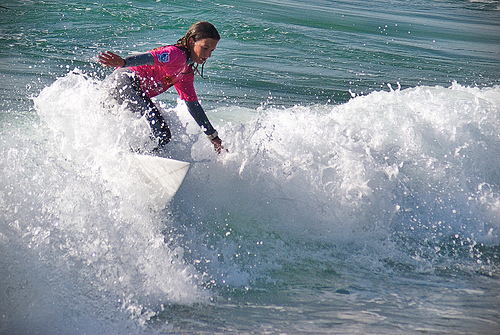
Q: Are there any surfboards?
A: Yes, there is a surfboard.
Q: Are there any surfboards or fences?
A: Yes, there is a surfboard.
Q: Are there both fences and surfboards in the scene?
A: No, there is a surfboard but no fences.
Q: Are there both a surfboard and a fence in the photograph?
A: No, there is a surfboard but no fences.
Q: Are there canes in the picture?
A: No, there are no canes.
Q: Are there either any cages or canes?
A: No, there are no canes or cages.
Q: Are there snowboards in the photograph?
A: No, there are no snowboards.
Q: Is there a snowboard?
A: No, there are no snowboards.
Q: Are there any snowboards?
A: No, there are no snowboards.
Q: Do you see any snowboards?
A: No, there are no snowboards.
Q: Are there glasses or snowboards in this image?
A: No, there are no snowboards or glasses.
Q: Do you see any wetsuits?
A: Yes, there is a wetsuit.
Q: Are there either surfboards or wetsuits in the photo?
A: Yes, there is a wetsuit.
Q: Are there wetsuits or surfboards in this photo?
A: Yes, there is a wetsuit.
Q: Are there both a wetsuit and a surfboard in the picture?
A: Yes, there are both a wetsuit and a surfboard.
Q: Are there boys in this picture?
A: No, there are no boys.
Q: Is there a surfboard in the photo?
A: Yes, there is a surfboard.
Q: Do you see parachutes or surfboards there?
A: Yes, there is a surfboard.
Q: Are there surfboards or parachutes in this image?
A: Yes, there is a surfboard.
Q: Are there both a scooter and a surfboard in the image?
A: No, there is a surfboard but no scooters.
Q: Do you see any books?
A: No, there are no books.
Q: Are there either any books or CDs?
A: No, there are no books or cds.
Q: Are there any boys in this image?
A: No, there are no boys.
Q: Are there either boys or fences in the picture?
A: No, there are no boys or fences.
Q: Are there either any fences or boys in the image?
A: No, there are no boys or fences.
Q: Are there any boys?
A: No, there are no boys.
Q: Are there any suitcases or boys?
A: No, there are no boys or suitcases.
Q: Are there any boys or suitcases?
A: No, there are no boys or suitcases.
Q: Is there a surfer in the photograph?
A: Yes, there is a surfer.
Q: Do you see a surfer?
A: Yes, there is a surfer.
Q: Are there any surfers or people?
A: Yes, there is a surfer.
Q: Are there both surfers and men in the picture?
A: No, there is a surfer but no men.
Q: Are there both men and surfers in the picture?
A: No, there is a surfer but no men.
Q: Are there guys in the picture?
A: No, there are no guys.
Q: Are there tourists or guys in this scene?
A: No, there are no guys or tourists.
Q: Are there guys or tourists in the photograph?
A: No, there are no guys or tourists.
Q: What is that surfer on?
A: The surfer is on the surfboard.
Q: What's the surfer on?
A: The surfer is on the surfboard.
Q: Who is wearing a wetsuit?
A: The surfer is wearing a wetsuit.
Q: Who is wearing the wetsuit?
A: The surfer is wearing a wetsuit.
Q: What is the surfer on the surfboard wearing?
A: The surfer is wearing a wetsuit.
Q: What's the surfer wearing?
A: The surfer is wearing a wetsuit.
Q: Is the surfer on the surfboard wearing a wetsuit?
A: Yes, the surfer is wearing a wetsuit.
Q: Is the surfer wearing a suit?
A: No, the surfer is wearing a wetsuit.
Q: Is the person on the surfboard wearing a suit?
A: No, the surfer is wearing a wetsuit.